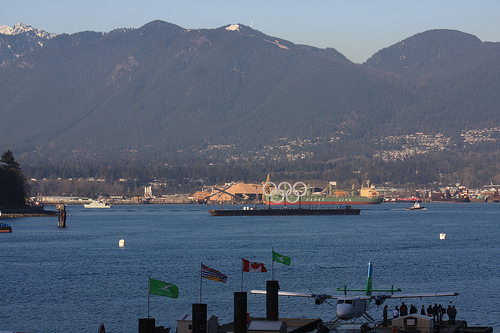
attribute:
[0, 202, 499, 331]
water — blue, calm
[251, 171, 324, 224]
logo — olympics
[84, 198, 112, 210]
motor boat — large, white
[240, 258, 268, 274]
flag — national, red, white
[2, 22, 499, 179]
mountain — big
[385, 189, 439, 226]
boat — smaller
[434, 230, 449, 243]
bouys — white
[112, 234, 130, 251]
bouys — white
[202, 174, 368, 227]
boat — black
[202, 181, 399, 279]
boat — small, tug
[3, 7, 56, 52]
peak — snow-covered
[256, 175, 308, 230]
symbol — olympic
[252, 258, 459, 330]
plane — sea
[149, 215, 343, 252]
water — large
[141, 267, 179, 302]
flag — green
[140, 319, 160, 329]
post — wooden